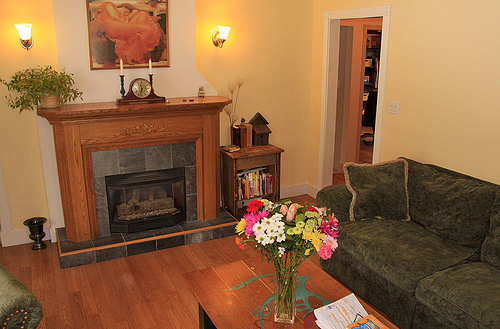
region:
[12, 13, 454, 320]
a living room scene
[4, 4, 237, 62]
lights on the wall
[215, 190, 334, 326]
flowers on the table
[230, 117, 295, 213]
a bookcase for books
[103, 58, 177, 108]
a clock on the mantle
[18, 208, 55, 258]
a vase by the fire place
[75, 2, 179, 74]
a picture on the wall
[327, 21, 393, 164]
an entrance way to another room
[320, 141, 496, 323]
a grey couch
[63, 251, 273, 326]
a wooden floor in the living room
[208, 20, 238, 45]
The light is on.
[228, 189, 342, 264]
The flowers are colorful.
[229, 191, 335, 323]
The vase is on the table.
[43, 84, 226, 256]
The fire place is off.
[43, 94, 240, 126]
The mantle is wood.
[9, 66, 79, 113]
The plant is on the mantle.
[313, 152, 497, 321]
The couch is green.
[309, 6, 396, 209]
The doorway is open.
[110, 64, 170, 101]
The clock is gold.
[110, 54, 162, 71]
The candles are white.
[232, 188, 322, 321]
vase of mixed flowers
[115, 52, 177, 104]
a clock on the fireplace mantle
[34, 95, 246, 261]
an electric fireplace in a room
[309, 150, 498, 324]
olive green cloth couch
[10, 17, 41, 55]
a light sconce on the wall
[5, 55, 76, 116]
a plant in a pot on a fireplace mantle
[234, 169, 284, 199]
small collection of books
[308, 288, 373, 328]
papers on a wooden coffee table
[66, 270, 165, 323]
hardwood floor in the living room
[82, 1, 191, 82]
painting on the wall over the fireplace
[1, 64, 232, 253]
A plant is on the fireplace mantle.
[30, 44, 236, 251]
A clock is on the fireplace mantle.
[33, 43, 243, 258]
Two candlesticks are on the fireplace mantle.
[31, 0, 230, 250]
A picture is hanging above the fireplace.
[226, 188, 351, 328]
The vase is clear.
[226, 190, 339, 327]
The vase is full.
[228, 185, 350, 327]
There are flowers in the vase.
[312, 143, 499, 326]
The couch is unoccupied.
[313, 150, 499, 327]
The couch is vacant.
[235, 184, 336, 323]
a vase of flowers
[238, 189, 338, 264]
multicolored flowers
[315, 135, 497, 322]
a green plush couch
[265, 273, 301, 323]
clear flower vase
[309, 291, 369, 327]
white papers on the coffee table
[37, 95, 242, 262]
a fireplace in the wall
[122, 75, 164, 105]
a clock on top of the fireplace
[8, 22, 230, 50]
lamps on the wall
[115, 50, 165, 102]
candle sticks on the fireplace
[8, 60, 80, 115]
a plant on the fireplace